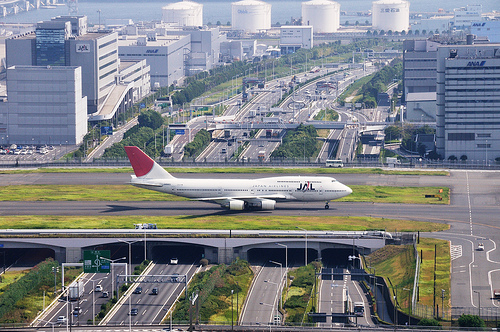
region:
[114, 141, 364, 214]
Boeing 747 jumbo jet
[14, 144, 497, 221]
Boeing airplane on taxi way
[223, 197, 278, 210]
wing mounted jet engines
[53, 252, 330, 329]
cars traveling on highways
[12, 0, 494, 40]
pacific ocean coastline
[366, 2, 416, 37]
large white storage silo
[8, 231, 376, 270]
tunnels underneath airplane taxiway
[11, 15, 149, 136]
JAL airline building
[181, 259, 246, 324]
grass and plant covered median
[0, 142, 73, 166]
small outdoor parking lot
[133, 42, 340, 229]
the plane is white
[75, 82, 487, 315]
the plane is white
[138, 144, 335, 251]
the plane is white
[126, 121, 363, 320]
the plane is white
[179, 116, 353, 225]
the plane is white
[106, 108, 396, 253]
the plane is white and visible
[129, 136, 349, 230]
the plane is white and visible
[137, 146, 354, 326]
the plane is white and visible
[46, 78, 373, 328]
the plane is white and visible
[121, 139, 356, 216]
white plane with red wing tip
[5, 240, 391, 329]
auto traffic under the bridge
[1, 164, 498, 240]
runway strip above bridge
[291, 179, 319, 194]
Japan Airlines logo on plane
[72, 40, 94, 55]
Japan Airlines logo on building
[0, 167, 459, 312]
strips of green grass around runway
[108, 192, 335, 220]
shadow of plane on ground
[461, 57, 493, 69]
gray and green logo on building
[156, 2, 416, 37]
4 round white structures in background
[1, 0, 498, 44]
view of water in background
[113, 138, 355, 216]
white plane on runway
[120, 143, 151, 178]
red tail on plane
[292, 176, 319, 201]
logo on side of plane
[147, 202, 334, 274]
runway on highway overpass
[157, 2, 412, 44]
four white tanks in background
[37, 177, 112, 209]
grass between two runways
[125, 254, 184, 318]
cars on highway in front of bridge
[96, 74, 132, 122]
ramp on side of building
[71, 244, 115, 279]
sign on pole above highway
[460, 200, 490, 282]
white lines on tarmac